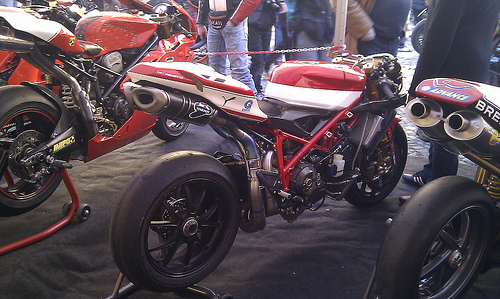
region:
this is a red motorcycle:
[108, 50, 408, 294]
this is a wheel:
[107, 149, 242, 294]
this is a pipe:
[129, 84, 220, 129]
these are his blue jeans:
[204, 23, 257, 98]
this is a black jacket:
[402, 0, 497, 109]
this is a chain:
[177, 40, 339, 64]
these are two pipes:
[400, 95, 499, 167]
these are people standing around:
[190, 0, 415, 101]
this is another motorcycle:
[2, 0, 197, 215]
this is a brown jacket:
[321, 0, 378, 54]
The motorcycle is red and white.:
[163, 49, 399, 104]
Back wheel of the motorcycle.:
[118, 153, 261, 285]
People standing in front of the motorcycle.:
[182, 4, 397, 66]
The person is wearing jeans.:
[192, 27, 249, 77]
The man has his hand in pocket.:
[211, 10, 241, 35]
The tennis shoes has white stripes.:
[398, 160, 430, 185]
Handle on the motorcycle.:
[382, 67, 404, 115]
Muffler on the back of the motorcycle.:
[402, 84, 477, 135]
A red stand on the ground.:
[51, 160, 89, 237]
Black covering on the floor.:
[251, 214, 376, 290]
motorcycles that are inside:
[157, 47, 472, 259]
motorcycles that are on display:
[85, 39, 499, 283]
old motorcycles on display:
[12, 85, 416, 297]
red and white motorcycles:
[37, 24, 428, 279]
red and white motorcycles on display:
[49, 16, 477, 292]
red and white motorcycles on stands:
[64, 10, 499, 260]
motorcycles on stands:
[61, 43, 497, 289]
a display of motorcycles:
[58, 35, 450, 246]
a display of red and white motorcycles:
[76, 22, 498, 277]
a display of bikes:
[28, 31, 496, 284]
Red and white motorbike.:
[110, 44, 410, 292]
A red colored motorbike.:
[1, 0, 198, 213]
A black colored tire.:
[373, 173, 493, 297]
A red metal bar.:
[0, 168, 80, 255]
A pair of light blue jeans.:
[206, 15, 257, 96]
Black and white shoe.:
[401, 164, 426, 186]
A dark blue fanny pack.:
[207, 6, 233, 31]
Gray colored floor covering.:
[0, 121, 242, 297]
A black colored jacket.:
[406, 0, 498, 97]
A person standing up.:
[343, 0, 412, 57]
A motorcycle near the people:
[111, 45, 404, 287]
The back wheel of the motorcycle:
[113, 152, 236, 288]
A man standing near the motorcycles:
[196, 4, 257, 91]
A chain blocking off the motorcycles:
[195, 45, 335, 55]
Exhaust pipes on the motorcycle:
[405, 97, 498, 153]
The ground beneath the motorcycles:
[1, 124, 498, 296]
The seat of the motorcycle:
[256, 97, 277, 113]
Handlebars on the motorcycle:
[331, 50, 393, 99]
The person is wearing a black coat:
[407, 1, 498, 92]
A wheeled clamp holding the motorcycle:
[1, 166, 89, 253]